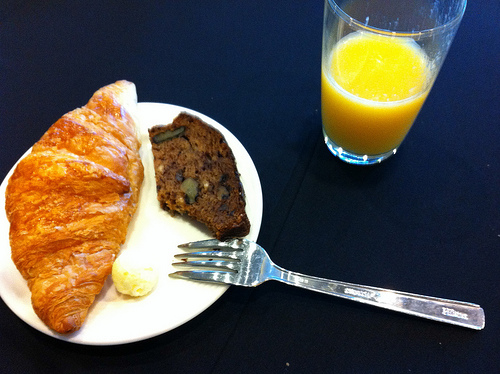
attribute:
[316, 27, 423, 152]
juice — orange, tall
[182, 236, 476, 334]
fork — silver, upside down, prong, handle, reflecting, tines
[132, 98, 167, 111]
plate — white, small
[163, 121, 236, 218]
meat — piece, brown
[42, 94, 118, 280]
bread — croissant, crumb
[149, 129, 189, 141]
pepper — green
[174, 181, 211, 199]
onion — small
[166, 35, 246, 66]
tablecloth — blue, black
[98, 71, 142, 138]
croissant — brown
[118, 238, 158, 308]
butter — ball, round, mound, yellow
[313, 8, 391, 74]
cup — glass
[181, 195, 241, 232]
meatloaf — piece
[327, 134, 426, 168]
glass — clear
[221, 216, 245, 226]
fruit cake — eaten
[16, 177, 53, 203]
pastry — crusty